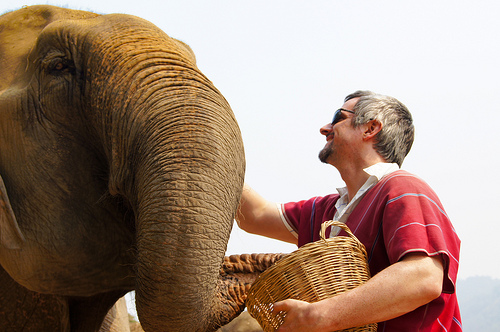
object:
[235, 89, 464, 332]
man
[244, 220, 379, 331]
basket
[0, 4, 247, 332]
elephant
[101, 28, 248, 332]
trunk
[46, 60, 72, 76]
right eye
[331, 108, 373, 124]
sunglasses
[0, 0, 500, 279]
sky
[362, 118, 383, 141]
left ear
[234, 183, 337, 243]
right arm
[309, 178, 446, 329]
left arm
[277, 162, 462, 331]
shirt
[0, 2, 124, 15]
hair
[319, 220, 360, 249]
handle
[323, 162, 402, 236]
collar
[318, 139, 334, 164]
goatee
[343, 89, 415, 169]
hair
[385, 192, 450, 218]
stripe